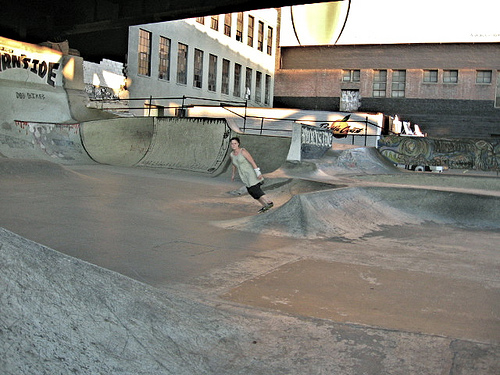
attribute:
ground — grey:
[4, 158, 499, 373]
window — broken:
[138, 28, 151, 76]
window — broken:
[156, 34, 169, 81]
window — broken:
[176, 40, 188, 84]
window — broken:
[193, 48, 203, 88]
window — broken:
[207, 53, 216, 90]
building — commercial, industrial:
[125, 0, 499, 143]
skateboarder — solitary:
[216, 130, 278, 218]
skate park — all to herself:
[1, 34, 498, 372]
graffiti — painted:
[375, 132, 497, 170]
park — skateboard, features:
[3, 92, 498, 374]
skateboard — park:
[256, 200, 274, 212]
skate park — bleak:
[10, 51, 457, 373]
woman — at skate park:
[222, 139, 275, 210]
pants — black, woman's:
[235, 181, 275, 206]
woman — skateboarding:
[228, 137, 273, 214]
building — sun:
[132, 6, 275, 110]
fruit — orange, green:
[329, 112, 361, 139]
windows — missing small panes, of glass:
[137, 32, 275, 95]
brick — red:
[276, 39, 496, 161]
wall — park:
[8, 24, 94, 179]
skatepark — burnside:
[4, 55, 499, 333]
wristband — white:
[249, 164, 262, 181]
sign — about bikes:
[14, 90, 52, 102]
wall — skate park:
[0, 37, 82, 128]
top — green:
[230, 153, 262, 188]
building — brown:
[278, 43, 498, 128]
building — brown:
[113, 32, 283, 114]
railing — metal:
[91, 94, 250, 121]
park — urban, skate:
[9, 52, 496, 362]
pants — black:
[228, 177, 289, 201]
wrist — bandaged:
[252, 162, 262, 180]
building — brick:
[287, 34, 452, 122]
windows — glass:
[334, 54, 490, 105]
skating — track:
[255, 189, 287, 230]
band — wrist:
[251, 161, 267, 180]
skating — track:
[251, 192, 281, 211]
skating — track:
[245, 197, 275, 223]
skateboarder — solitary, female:
[220, 132, 277, 216]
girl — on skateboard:
[222, 130, 279, 217]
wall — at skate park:
[8, 50, 90, 177]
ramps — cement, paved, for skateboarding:
[286, 166, 406, 282]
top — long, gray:
[229, 151, 262, 181]